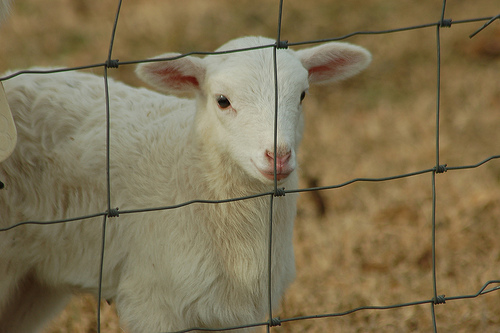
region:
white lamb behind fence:
[18, 46, 365, 324]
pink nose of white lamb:
[253, 142, 290, 164]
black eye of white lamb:
[211, 90, 236, 118]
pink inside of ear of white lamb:
[143, 50, 205, 100]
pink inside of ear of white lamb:
[298, 52, 364, 79]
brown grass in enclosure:
[311, 201, 419, 294]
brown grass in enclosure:
[374, 44, 424, 166]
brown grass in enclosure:
[7, 5, 219, 43]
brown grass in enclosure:
[382, 8, 493, 242]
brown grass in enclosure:
[306, 158, 476, 318]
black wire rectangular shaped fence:
[35, 10, 485, 320]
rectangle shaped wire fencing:
[256, 162, 467, 328]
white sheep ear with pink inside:
[127, 45, 210, 100]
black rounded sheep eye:
[210, 90, 233, 115]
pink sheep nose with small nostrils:
[262, 137, 293, 168]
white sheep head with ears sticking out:
[128, 23, 370, 196]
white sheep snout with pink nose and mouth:
[252, 120, 297, 191]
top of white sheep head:
[197, 25, 297, 65]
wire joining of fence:
[95, 200, 121, 225]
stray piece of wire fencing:
[426, 1, 499, 39]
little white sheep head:
[157, 0, 362, 230]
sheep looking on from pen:
[93, 0, 398, 230]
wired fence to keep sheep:
[218, 167, 400, 224]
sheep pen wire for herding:
[275, 172, 432, 207]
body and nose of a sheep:
[39, 138, 385, 226]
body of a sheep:
[19, 83, 205, 303]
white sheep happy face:
[126, 22, 363, 224]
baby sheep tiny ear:
[132, 42, 208, 98]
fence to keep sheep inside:
[88, 186, 364, 321]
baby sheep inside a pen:
[34, 72, 391, 240]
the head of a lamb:
[135, 30, 387, 191]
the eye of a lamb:
[208, 89, 239, 116]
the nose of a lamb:
[258, 140, 295, 169]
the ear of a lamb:
[119, 50, 213, 100]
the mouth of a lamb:
[249, 155, 299, 183]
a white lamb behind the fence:
[0, 28, 382, 331]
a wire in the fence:
[98, 0, 130, 62]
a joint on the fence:
[98, 200, 122, 225]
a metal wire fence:
[0, 0, 498, 327]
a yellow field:
[1, 0, 498, 332]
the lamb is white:
[30, 47, 348, 332]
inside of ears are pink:
[147, 52, 365, 69]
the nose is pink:
[256, 137, 295, 163]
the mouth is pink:
[249, 155, 315, 195]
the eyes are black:
[212, 87, 310, 110]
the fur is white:
[17, 115, 219, 287]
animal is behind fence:
[17, 34, 368, 315]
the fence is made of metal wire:
[268, 148, 297, 207]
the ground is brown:
[326, 222, 436, 309]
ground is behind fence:
[375, 33, 498, 318]